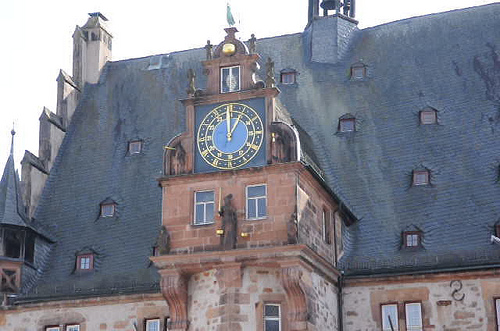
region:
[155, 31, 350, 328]
A clock tower on the building.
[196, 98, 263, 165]
A clock on the tower.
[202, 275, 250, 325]
Bricks on the building.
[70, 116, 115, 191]
The singles are grey.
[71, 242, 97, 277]
A window on the roof.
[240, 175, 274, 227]
A window on the clock tower.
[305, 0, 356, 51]
A bell on top of the building.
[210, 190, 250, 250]
The statue of a woman on the tower.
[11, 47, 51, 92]
The sky is overcast.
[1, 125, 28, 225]
Spire on the building.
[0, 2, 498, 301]
gray roof on building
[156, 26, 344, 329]
tower on building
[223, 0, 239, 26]
gray bird on top of tower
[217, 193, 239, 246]
brown statue on tower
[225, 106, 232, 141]
gold minute hand on clock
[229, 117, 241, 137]
gold hour hand on clock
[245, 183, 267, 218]
window to the right of window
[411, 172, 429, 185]
small windows on roof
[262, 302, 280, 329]
window on tower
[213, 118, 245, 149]
center of clock face is blue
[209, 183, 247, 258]
statue on building ledge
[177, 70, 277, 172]
large clock on front of building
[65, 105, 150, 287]
windows scattered on roof of house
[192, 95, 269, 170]
blue clock with gold hands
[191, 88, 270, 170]
clock with roman numerals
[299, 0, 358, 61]
chimney on top of roof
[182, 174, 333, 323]
red brick building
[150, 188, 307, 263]
three statues under clock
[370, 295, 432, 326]
white windows with brown frames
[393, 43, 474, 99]
black shingled roof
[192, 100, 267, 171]
red gold and blue clock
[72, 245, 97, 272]
small window on a roof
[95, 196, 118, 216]
small window on a roof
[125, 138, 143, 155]
small window on a roof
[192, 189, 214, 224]
an exterior window on a building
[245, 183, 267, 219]
an exterior window on a building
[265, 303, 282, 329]
an exterior window on a building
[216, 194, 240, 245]
a stone statue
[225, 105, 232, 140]
large hand of a clock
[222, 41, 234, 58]
a golden sphere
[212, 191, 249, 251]
statue holding a scale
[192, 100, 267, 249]
statue under a clock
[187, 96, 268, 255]
clock over a statue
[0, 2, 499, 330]
building under a clear sky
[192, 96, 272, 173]
clock reads 1:00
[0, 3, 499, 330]
building with lots of windows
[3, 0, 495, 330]
roof on a building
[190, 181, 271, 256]
windows behind a statue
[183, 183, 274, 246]
statue in front of windows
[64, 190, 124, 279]
window beneath a window